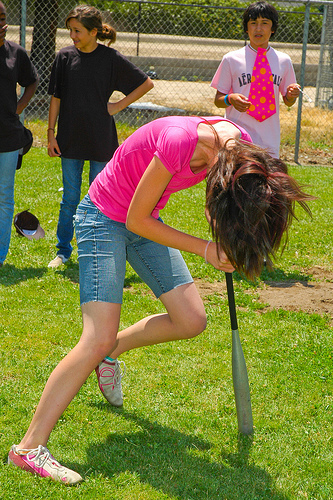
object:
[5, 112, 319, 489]
woman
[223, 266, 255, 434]
bat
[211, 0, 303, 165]
boy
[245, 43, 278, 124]
tie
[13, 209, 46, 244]
cap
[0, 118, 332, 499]
grass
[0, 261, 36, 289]
shadow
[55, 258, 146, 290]
shadow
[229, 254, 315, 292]
shadow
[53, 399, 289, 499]
shadow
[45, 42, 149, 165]
shirt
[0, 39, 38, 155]
shirt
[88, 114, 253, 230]
shirt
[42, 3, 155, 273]
woman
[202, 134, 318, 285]
hair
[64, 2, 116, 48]
hair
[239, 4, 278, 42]
hair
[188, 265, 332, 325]
dirt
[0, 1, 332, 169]
fence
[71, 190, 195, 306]
shorts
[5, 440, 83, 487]
shoe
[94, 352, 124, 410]
shoe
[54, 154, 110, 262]
jeans